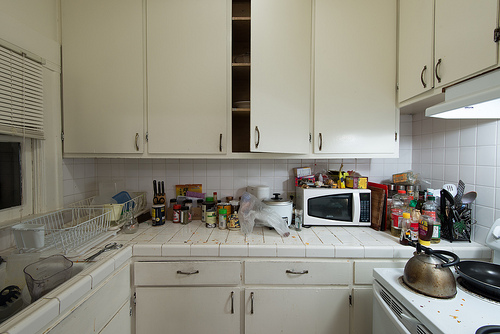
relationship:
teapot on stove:
[402, 241, 460, 300] [369, 225, 500, 333]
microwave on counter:
[296, 186, 374, 227] [136, 206, 486, 259]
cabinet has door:
[146, 2, 315, 160] [246, 0, 315, 156]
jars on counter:
[167, 191, 240, 233] [136, 206, 486, 259]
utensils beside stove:
[440, 181, 476, 243] [369, 225, 500, 333]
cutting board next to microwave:
[370, 180, 389, 231] [296, 186, 374, 227]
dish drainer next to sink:
[9, 205, 117, 259] [0, 238, 87, 330]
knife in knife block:
[151, 178, 158, 197] [152, 193, 167, 210]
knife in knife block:
[158, 181, 163, 197] [152, 193, 167, 210]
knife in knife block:
[161, 182, 168, 197] [152, 193, 167, 210]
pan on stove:
[459, 256, 500, 302] [369, 225, 500, 333]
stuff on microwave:
[292, 164, 369, 190] [296, 186, 374, 227]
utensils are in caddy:
[440, 181, 476, 243] [446, 207, 474, 241]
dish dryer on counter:
[9, 205, 117, 259] [66, 216, 156, 272]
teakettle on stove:
[402, 241, 460, 300] [369, 225, 500, 333]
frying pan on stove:
[459, 256, 500, 302] [369, 225, 500, 333]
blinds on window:
[0, 36, 46, 140] [0, 41, 39, 223]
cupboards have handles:
[63, 5, 398, 161] [253, 125, 262, 150]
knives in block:
[152, 179, 167, 197] [152, 193, 167, 210]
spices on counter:
[169, 198, 193, 228] [136, 206, 486, 259]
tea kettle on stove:
[402, 241, 460, 300] [369, 225, 500, 333]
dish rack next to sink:
[66, 190, 150, 230] [0, 238, 87, 330]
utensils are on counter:
[440, 181, 476, 243] [136, 206, 486, 259]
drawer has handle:
[132, 258, 377, 287] [177, 268, 201, 279]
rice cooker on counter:
[261, 192, 294, 230] [136, 206, 486, 259]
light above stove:
[425, 72, 499, 120] [369, 225, 500, 333]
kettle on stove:
[402, 241, 460, 300] [369, 225, 500, 333]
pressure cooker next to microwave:
[261, 192, 294, 230] [296, 186, 374, 227]